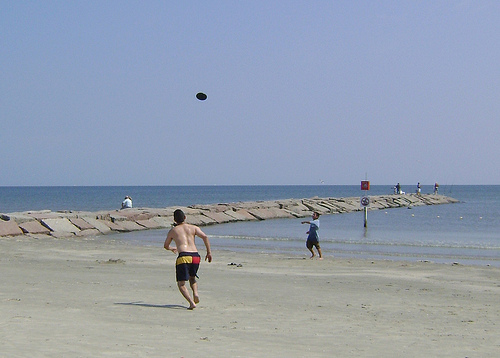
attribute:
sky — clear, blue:
[2, 2, 497, 184]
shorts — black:
[175, 250, 201, 282]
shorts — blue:
[304, 234, 323, 249]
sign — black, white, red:
[358, 193, 373, 209]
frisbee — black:
[196, 91, 208, 99]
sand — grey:
[230, 273, 495, 354]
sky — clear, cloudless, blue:
[259, 27, 447, 141]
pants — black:
[305, 237, 320, 251]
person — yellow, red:
[158, 205, 215, 310]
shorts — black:
[165, 247, 205, 283]